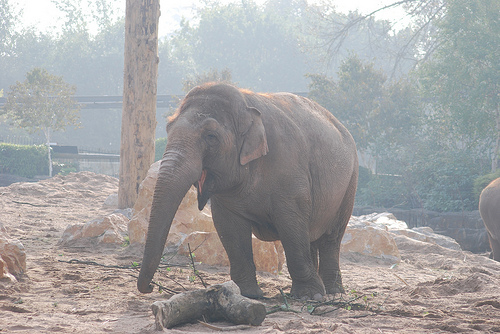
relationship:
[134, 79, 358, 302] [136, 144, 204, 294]
animal has trunk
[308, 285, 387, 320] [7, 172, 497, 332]
twigs on sand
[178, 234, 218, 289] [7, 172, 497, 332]
twigs on sand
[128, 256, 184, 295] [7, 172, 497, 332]
twigs on sand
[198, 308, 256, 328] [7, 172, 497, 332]
twigs on sand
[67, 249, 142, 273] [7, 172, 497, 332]
twigs on sand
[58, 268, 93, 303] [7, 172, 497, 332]
foot prints in sand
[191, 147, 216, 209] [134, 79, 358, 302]
mouth of animal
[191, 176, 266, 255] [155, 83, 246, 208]
whimsical on face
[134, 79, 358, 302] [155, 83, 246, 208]
animal has face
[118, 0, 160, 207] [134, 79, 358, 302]
pole beside animal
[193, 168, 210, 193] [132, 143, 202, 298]
tongue up under trunk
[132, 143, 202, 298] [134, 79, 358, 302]
trunk of animal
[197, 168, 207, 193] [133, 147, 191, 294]
tongue up under trunk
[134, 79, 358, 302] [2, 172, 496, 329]
animal standing on ground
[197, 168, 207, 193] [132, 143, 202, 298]
tongue under trunk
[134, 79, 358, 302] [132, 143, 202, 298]
animal has trunk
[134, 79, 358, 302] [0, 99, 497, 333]
animal in enclosure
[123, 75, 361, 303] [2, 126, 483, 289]
animal in enclosure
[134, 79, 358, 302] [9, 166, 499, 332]
animal in area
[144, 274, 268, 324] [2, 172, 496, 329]
log on ground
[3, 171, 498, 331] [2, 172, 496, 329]
dirt on ground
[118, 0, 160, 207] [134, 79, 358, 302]
pole near animal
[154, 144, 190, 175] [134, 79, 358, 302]
wrinkles are on animal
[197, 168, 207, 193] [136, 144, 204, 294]
tongue under trunk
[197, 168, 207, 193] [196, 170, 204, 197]
tongue under trunk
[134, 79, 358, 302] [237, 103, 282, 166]
animal has ears